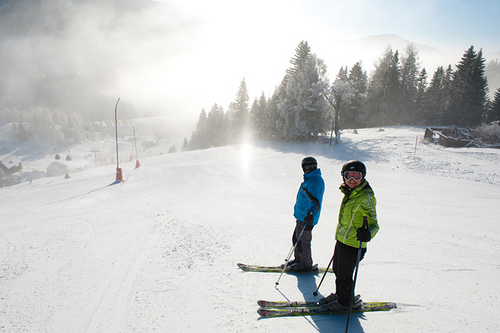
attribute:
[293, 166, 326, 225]
jacket — medium blue, green, blue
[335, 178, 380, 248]
jacket — bright green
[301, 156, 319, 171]
cap — blue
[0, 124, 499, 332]
snow — white color, clear, white, powdery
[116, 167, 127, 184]
cone — orange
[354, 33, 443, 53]
mountain — shining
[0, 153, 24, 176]
house — small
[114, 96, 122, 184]
pole — tall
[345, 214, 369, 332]
ski pole — long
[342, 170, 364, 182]
ski goggles — orange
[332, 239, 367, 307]
pants — black, snow pants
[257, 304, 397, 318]
snow ski — yellow